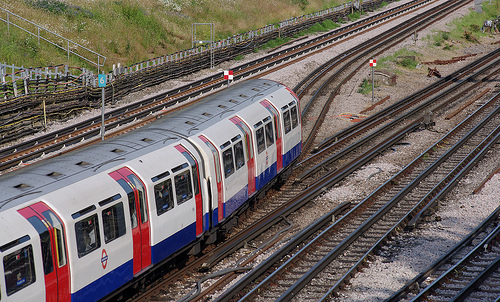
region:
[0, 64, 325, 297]
the train on the tracks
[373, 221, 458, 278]
the gravel beside the tracks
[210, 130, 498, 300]
the tracks are empty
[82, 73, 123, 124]
the blue sign beside the tracks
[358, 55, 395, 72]
the red and white sign beside the tracks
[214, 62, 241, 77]
the red and white sign beside the tracks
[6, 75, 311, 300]
the train is red white and blue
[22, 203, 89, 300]
the door on the train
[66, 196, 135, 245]
the window on the train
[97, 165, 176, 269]
the door on the train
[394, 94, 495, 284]
empty train tracks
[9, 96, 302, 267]
train on the tracks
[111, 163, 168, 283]
red doors on the train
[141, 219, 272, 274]
blue stripe at the bottom of the train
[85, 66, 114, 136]
green sign by the tracks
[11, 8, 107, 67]
rail going up the hill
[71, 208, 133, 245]
windows on the train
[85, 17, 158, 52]
grass growing on the hill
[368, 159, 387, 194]
gravel in between the tracks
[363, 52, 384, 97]
red and white sign by the tracks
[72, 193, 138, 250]
Windows on the side of the train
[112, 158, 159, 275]
Red doors on the side of the train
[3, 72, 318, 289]
A primarily grey train on the train tracks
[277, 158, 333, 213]
Train tracks beneath the train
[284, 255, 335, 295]
Wooden planks in between the rails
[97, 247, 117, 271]
A small red logo on the train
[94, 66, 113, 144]
A tall sign by the train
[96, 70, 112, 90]
A small blue sign on the metal pole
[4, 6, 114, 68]
A grey fence beside the train tracks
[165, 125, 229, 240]
Two red doors on the side of a train.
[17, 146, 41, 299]
Two red doors on the side of a train.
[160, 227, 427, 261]
Two red doors on the side of a train.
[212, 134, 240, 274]
Two red doors on the side of a train.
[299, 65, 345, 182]
the split in the train tracks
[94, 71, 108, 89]
the blue sign on the railyard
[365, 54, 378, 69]
the red and white checkered sign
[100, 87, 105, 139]
the pole of the blue sign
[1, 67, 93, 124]
the fence behind the train yard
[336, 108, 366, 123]
the spraypaint on the gorund near the tracks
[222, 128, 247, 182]
the window on the train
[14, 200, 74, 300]
ther red doors on the train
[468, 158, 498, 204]
the rail on the ground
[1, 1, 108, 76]
the hand rail going up the hill